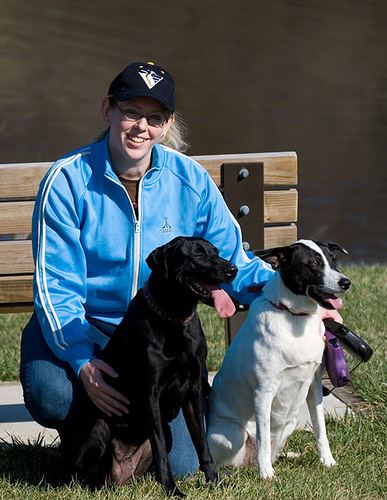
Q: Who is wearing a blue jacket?
A: The woman.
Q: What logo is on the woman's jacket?
A: Atari.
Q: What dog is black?
A: Left dog.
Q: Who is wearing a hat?
A: The woman.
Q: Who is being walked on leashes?
A: The two dogs.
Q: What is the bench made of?
A: Wood.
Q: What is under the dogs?
A: Grass.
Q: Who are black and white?
A: Dogs.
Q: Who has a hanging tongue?
A: The dog.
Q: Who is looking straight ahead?
A: The dog.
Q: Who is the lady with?
A: Two dogs.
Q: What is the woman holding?
A: Her pets.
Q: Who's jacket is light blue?
A: The lady's.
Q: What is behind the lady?
A: A wooden post.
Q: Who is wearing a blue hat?
A: A woman.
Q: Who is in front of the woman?
A: A black and white dog.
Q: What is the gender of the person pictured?
A: Female.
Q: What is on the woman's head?
A: Baseball cap.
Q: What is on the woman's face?
A: Eye glasses.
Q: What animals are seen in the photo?
A: Dogs.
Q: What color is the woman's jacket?
A: Blue.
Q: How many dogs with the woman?
A: Two.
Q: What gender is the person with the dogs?
A: Female.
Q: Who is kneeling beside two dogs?
A: A woman.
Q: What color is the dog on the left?
A: Black.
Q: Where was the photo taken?
A: Park.